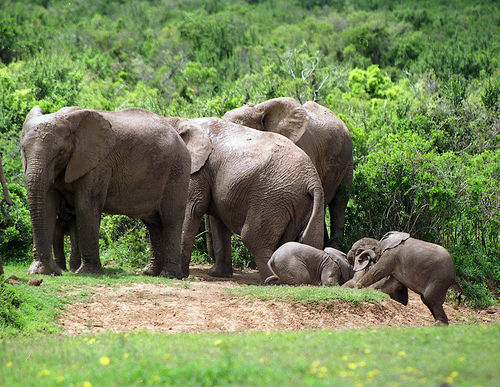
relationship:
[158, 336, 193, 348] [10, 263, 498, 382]
grass in field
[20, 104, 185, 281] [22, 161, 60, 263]
elephant has trunk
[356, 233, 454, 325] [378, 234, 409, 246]
elephant has ear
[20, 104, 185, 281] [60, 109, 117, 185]
elephant has ear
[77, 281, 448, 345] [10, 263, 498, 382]
dirt on ground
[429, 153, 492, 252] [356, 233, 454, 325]
bush near elephant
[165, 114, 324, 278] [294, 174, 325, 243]
elephant has tail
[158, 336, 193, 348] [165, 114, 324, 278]
grass near elephant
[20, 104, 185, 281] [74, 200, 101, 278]
elephant has leg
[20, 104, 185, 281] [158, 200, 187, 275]
elephant has leg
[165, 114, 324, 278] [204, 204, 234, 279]
elephant has leg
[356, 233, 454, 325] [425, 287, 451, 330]
elephant has leg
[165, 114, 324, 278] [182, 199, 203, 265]
elephant has leg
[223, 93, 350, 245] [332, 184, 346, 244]
elephant has leg